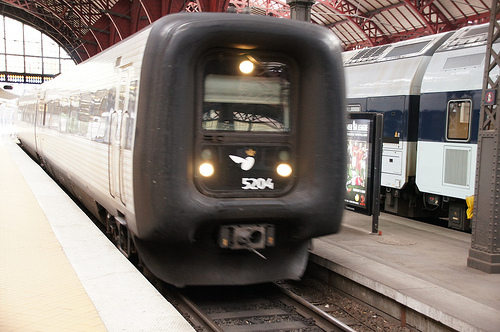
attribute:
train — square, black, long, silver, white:
[2, 14, 347, 291]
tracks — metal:
[164, 283, 354, 330]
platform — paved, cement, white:
[3, 135, 195, 332]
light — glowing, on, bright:
[199, 161, 215, 180]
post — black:
[373, 113, 382, 234]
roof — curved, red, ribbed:
[2, 0, 500, 68]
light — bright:
[276, 164, 293, 178]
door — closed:
[107, 66, 128, 206]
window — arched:
[1, 15, 79, 88]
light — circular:
[239, 59, 253, 75]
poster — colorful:
[347, 119, 372, 209]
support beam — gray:
[465, 0, 500, 274]